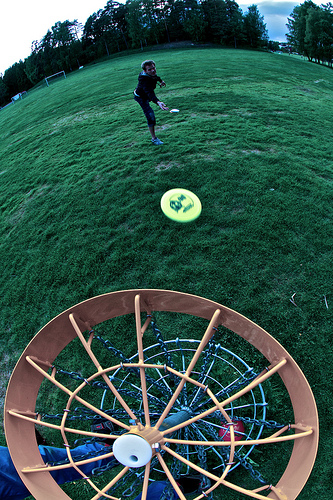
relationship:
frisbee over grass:
[129, 154, 238, 254] [30, 68, 252, 284]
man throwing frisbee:
[141, 65, 206, 177] [155, 190, 244, 261]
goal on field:
[43, 276, 297, 498] [12, 46, 297, 368]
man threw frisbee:
[133, 59, 167, 146] [159, 185, 204, 224]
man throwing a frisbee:
[133, 59, 167, 146] [157, 187, 202, 223]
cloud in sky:
[236, 1, 300, 43] [0, 1, 302, 74]